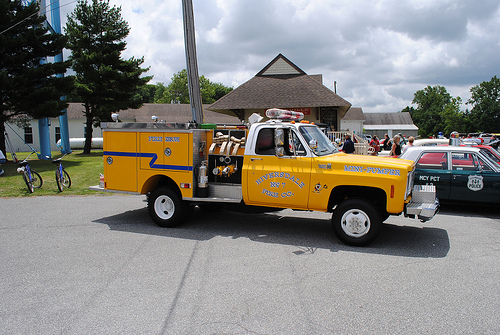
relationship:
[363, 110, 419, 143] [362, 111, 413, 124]
building has roof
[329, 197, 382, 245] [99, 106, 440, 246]
tire on bottom of truck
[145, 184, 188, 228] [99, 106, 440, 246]
tire on bottom of truck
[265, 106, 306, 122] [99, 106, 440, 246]
light bar on top of truck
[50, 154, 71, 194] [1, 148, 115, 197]
bicycle parked on grass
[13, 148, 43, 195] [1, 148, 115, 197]
bicycle parked on grass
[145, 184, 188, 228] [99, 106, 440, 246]
tire on back of truck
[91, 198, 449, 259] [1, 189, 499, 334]
shadow on top of road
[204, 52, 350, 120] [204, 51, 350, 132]
roof on top of building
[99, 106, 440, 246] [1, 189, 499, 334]
truck on top of road